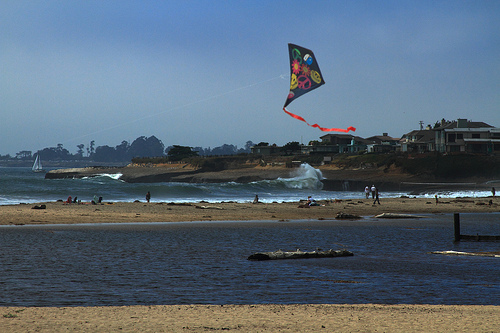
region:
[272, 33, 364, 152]
kite flying in the air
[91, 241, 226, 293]
body of water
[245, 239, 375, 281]
log floating on water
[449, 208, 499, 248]
pier in water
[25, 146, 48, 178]
sail boat with white sails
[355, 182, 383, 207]
people water along shoreline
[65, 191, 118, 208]
people sitting at shoreline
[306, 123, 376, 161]
house on hillside at a distance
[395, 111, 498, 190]
house on hillside at a distance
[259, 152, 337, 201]
waves splashing onto land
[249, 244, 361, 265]
A tree log in the water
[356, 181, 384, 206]
Two men walking on the beach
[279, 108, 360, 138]
A red ribbon on the end of a kite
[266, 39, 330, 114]
A kite in mid-air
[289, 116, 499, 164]
Homes near the beach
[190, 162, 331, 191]
Sea waves slamming against the shore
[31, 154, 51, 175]
A white sailing boat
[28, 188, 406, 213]
Many people on the beach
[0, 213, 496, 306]
Dark blue water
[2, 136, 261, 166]
Silhouetted trees in the background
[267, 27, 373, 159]
kite with long red tail floating in the wind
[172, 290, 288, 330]
beach where water meets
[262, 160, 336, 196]
wave breaking on the shore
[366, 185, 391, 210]
distant person walking on the beach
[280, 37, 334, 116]
kite with smiley faces on it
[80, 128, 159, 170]
distant tree line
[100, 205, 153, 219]
beach with gold sand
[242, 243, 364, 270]
sand bar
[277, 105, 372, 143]
red tail of kite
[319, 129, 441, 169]
houses in the distance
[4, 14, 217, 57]
Patch of blue sky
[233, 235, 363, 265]
A log in the water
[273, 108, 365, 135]
Red kite tail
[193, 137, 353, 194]
Wave crashing into sea wall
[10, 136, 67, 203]
Sailboat on the water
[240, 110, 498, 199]
Row of beach side homes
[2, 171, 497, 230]
Strip of beach between calm and rough waters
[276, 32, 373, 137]
Black kite with colorful design and red tail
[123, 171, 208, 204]
Person watching the surf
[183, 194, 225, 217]
Piece of driftwood on the beach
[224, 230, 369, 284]
tree log in the water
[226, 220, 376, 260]
tree log in the water